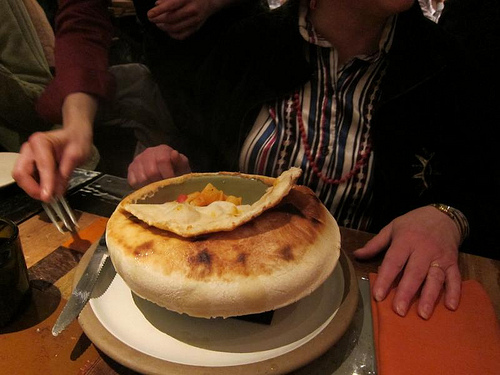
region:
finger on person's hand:
[438, 254, 467, 312]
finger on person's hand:
[417, 249, 441, 327]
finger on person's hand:
[389, 243, 424, 319]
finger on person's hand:
[373, 232, 410, 298]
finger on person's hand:
[348, 211, 400, 261]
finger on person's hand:
[163, 140, 194, 173]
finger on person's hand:
[146, 139, 174, 178]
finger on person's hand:
[57, 132, 94, 178]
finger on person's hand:
[23, 123, 54, 198]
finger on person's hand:
[121, 157, 139, 190]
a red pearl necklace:
[288, 90, 377, 181]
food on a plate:
[118, 175, 337, 303]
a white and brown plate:
[81, 256, 361, 368]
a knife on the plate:
[48, 239, 117, 337]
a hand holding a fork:
[29, 34, 91, 235]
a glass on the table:
[5, 227, 43, 303]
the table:
[376, 318, 498, 354]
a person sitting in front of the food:
[224, 22, 478, 314]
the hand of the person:
[360, 188, 486, 324]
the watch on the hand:
[435, 196, 470, 233]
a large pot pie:
[59, 89, 414, 374]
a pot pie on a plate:
[58, 157, 287, 372]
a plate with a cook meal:
[90, 94, 382, 374]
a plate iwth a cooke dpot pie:
[64, 161, 289, 347]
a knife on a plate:
[59, 164, 190, 354]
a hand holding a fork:
[19, 115, 153, 290]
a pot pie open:
[111, 153, 416, 370]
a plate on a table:
[105, 143, 405, 371]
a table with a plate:
[32, 148, 399, 353]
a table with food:
[65, 168, 350, 372]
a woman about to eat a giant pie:
[103, 5, 471, 336]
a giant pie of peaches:
[103, 172, 354, 322]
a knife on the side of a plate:
[33, 233, 124, 344]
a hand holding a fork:
[9, 128, 93, 236]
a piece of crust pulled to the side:
[120, 203, 320, 263]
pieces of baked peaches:
[176, 185, 241, 210]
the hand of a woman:
[352, 196, 472, 323]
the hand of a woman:
[122, 145, 197, 187]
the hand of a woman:
[13, 100, 101, 214]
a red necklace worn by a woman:
[283, 53, 376, 188]